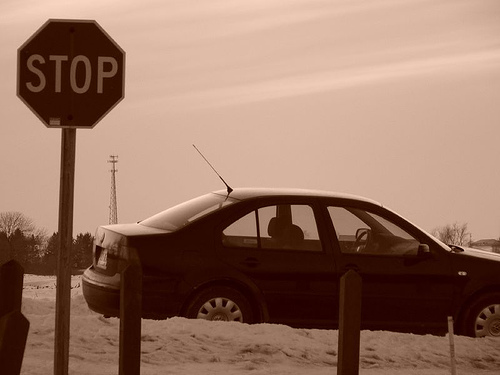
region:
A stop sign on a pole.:
[16, 17, 128, 370]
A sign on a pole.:
[14, 18, 125, 372]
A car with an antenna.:
[82, 143, 499, 337]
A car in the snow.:
[79, 143, 497, 339]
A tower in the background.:
[105, 148, 120, 225]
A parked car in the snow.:
[80, 141, 499, 335]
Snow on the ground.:
[21, 272, 497, 374]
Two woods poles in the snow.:
[117, 260, 364, 373]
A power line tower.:
[106, 151, 120, 223]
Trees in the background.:
[0, 208, 474, 277]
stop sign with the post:
[18, 13, 130, 195]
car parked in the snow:
[82, 184, 492, 353]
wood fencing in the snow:
[118, 268, 374, 371]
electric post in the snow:
[103, 151, 127, 219]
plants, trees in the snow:
[4, 217, 51, 262]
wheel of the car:
[193, 284, 276, 327]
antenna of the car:
[191, 137, 245, 199]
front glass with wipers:
[368, 191, 465, 255]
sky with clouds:
[226, 33, 408, 126]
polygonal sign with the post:
[12, 18, 126, 139]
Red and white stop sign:
[14, 16, 129, 131]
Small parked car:
[89, 160, 496, 336]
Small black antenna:
[186, 137, 242, 199]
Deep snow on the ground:
[23, 313, 494, 372]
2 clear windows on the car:
[221, 198, 430, 266]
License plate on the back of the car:
[96, 246, 111, 273]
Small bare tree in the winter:
[432, 220, 475, 248]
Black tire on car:
[191, 281, 261, 321]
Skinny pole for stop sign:
[53, 123, 79, 374]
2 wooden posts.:
[110, 253, 362, 374]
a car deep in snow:
[79, 185, 499, 359]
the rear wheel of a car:
[182, 275, 252, 335]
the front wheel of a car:
[461, 288, 497, 348]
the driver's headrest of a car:
[265, 210, 280, 235]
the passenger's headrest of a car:
[281, 223, 308, 245]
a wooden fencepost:
[332, 266, 372, 371]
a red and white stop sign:
[13, 13, 132, 140]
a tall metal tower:
[105, 145, 126, 220]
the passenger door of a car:
[317, 198, 454, 324]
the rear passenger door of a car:
[226, 195, 338, 348]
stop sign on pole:
[11, 15, 131, 369]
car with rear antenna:
[80, 130, 499, 324]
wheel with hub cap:
[188, 280, 260, 335]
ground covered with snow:
[25, 275, 499, 373]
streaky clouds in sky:
[111, 13, 488, 112]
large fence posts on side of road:
[104, 241, 376, 373]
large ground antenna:
[91, 151, 122, 228]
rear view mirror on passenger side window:
[306, 199, 443, 281]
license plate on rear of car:
[81, 221, 138, 304]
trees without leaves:
[412, 218, 494, 258]